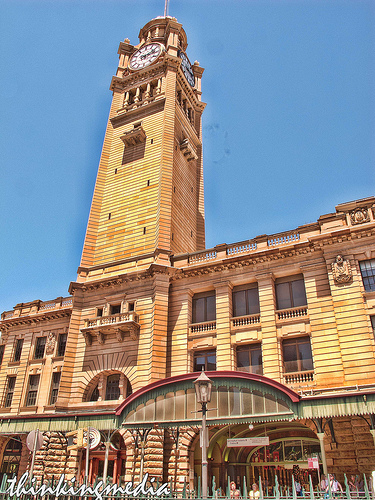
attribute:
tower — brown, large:
[52, 6, 215, 411]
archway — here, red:
[108, 360, 304, 431]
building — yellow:
[0, 2, 374, 496]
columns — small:
[26, 420, 237, 487]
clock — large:
[125, 34, 167, 75]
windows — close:
[183, 259, 326, 399]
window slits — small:
[116, 72, 169, 119]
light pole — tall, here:
[182, 357, 229, 499]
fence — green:
[224, 460, 366, 499]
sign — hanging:
[222, 424, 285, 451]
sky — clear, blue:
[202, 13, 367, 231]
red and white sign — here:
[300, 446, 323, 478]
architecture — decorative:
[18, 346, 154, 413]